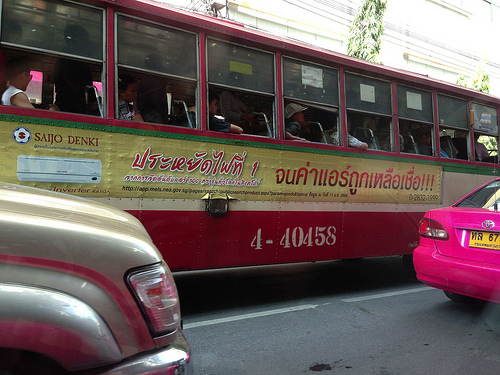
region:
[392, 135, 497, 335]
A hot pink Toyota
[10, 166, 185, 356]
Front of a biege car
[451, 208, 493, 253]
Yellow and black license plate on car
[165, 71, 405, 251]
Red and green bus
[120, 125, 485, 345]
Vehicles in traffic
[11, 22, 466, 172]
All of the windows are open in the bus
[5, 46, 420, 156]
People looking out the window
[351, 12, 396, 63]
Tree behind the bus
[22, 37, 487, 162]
People in bus are Asian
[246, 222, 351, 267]
Bus number 4-40458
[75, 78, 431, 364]
picture taken outdoors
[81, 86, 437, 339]
picture taken during the day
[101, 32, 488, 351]
a bus full of people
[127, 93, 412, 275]
the bus is yellow and red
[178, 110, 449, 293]
the windows of the bus are open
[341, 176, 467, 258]
a bright pink car next to the buss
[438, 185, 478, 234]
the license plate is yellow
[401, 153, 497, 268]
the car is a toyota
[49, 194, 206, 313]
another car next to the bus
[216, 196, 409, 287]
the buss says 4-40458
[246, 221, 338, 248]
a number written in white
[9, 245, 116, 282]
a bright pink stripe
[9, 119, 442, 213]
an add in multiple languages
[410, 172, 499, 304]
a bright pink toyota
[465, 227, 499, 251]
a bright yellow license plate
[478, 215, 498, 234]
a silver company logo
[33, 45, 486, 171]
a row of open windows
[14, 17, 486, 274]
a red city bus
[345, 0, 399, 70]
a tall green plant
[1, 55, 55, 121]
a person in a white shirt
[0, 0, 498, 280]
The red, green and white bus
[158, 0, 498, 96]
The building behind the bus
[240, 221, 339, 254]
The white numbers on the bus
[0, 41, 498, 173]
The open windows of the bus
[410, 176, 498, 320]
The pink toyota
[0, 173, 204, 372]
The gold car behind the pink one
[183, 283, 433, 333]
The white line on the road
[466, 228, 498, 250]
The yellow license plate on the pink car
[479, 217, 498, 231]
The silver toyota emblem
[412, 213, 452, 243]
The brake light of the pink car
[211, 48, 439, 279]
side of city bus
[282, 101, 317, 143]
person sitting in bus seat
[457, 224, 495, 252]
license plate on car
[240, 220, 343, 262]
numbers on side of bus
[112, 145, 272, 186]
asian charachters on bus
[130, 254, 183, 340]
headlight on front of vehicle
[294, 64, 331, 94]
white paper in window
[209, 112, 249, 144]
arm on edge of window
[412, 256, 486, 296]
pink bumper on car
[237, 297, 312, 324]
white line in street